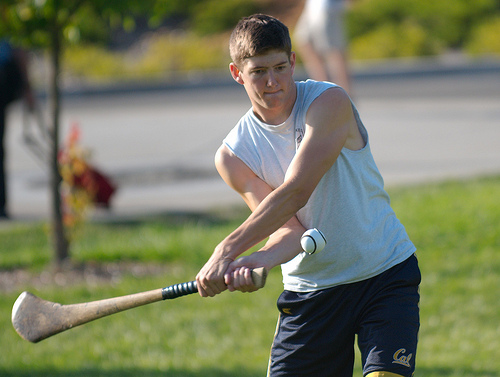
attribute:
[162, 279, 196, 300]
grip — blue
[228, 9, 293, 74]
hair — dark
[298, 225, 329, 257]
black stripes ball — stripe, white , black 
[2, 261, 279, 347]
wooden bat — wooden 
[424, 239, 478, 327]
green grass — green 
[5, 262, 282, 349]
bat — wood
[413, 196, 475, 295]
he grass is green — lush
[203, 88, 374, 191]
boy's shirt — sleeveless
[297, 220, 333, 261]
white, small ball — white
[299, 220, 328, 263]
white, small ball — white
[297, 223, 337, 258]
small ball — white